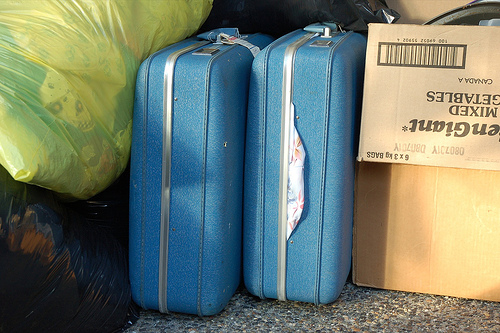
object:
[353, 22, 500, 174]
box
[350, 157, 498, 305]
box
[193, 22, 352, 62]
handles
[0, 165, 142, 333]
black bag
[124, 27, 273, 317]
blue suitcase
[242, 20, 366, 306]
blue suitcase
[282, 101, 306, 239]
fabric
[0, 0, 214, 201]
bag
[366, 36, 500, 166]
writing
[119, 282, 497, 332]
ground